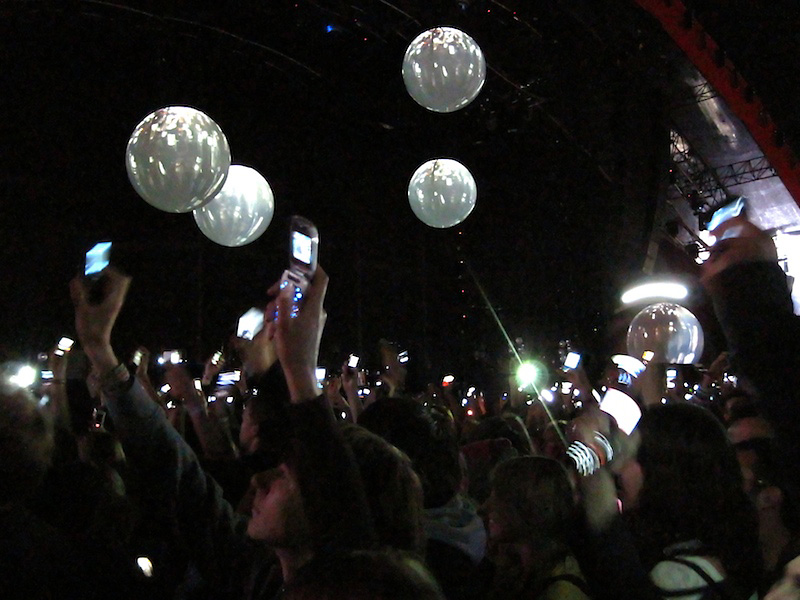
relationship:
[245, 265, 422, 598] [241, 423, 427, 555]
man has head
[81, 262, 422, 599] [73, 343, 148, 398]
man wearing watch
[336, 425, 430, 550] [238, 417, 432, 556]
hair of man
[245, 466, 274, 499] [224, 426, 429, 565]
nose of man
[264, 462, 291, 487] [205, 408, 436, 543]
eyes of man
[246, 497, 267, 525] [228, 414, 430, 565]
mouth of man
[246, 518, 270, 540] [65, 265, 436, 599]
chin of man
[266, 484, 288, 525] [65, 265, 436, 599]
cheek of man